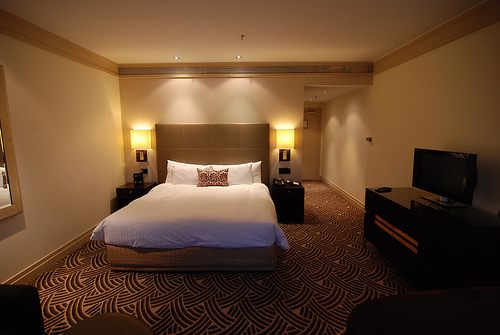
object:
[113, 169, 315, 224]
nightstands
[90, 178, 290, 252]
comforter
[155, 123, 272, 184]
headbed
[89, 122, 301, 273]
bed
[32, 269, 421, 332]
carpet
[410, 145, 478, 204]
screen tv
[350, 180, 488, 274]
dresser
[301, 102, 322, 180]
door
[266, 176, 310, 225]
night stand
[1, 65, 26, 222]
framed mirror